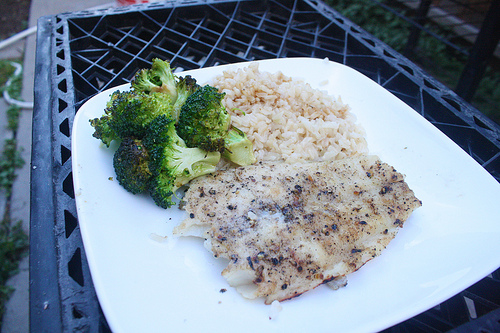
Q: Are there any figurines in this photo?
A: No, there are no figurines.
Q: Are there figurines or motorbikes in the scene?
A: No, there are no figurines or motorbikes.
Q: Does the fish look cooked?
A: Yes, the fish is cooked.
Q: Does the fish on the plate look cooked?
A: Yes, the fish is cooked.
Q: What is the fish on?
A: The fish is on the plate.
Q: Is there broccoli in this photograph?
A: Yes, there is broccoli.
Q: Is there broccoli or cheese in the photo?
A: Yes, there is broccoli.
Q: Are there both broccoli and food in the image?
A: Yes, there are both broccoli and food.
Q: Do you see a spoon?
A: No, there are no spoons.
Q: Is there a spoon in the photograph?
A: No, there are no spoons.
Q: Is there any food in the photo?
A: Yes, there is food.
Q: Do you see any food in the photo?
A: Yes, there is food.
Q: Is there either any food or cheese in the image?
A: Yes, there is food.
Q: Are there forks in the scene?
A: No, there are no forks.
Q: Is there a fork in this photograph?
A: No, there are no forks.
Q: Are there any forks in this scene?
A: No, there are no forks.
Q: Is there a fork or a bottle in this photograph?
A: No, there are no forks or bottles.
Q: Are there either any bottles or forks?
A: No, there are no forks or bottles.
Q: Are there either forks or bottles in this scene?
A: No, there are no forks or bottles.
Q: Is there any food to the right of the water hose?
A: Yes, there is food to the right of the water hose.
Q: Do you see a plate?
A: Yes, there is a plate.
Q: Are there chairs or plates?
A: Yes, there is a plate.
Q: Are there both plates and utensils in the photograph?
A: No, there is a plate but no utensils.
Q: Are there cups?
A: No, there are no cups.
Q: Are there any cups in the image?
A: No, there are no cups.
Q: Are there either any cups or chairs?
A: No, there are no cups or chairs.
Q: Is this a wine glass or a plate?
A: This is a plate.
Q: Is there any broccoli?
A: Yes, there is broccoli.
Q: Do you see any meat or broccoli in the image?
A: Yes, there is broccoli.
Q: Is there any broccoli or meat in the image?
A: Yes, there is broccoli.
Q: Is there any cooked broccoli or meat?
A: Yes, there is cooked broccoli.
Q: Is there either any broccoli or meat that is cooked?
A: Yes, the broccoli is cooked.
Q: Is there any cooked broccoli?
A: Yes, there is cooked broccoli.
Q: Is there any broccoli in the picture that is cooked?
A: Yes, there is broccoli that is cooked.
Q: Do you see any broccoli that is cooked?
A: Yes, there is broccoli that is cooked.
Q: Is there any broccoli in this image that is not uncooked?
A: Yes, there is cooked broccoli.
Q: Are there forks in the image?
A: No, there are no forks.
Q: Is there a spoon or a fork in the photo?
A: No, there are no forks or spoons.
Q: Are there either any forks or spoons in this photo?
A: No, there are no forks or spoons.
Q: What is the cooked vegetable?
A: The vegetable is broccoli.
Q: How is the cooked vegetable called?
A: The vegetable is broccoli.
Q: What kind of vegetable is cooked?
A: The vegetable is broccoli.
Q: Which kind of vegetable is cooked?
A: The vegetable is broccoli.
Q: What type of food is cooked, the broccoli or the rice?
A: The broccoli is cooked.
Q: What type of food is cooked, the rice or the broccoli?
A: The broccoli is cooked.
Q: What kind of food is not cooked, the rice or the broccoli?
A: The rice is not cooked.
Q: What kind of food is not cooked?
A: The food is rice.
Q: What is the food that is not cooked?
A: The food is rice.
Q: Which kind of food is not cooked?
A: The food is rice.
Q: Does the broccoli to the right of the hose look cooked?
A: Yes, the broccoli is cooked.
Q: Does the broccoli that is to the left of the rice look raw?
A: No, the broccoli is cooked.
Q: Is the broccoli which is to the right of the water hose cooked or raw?
A: The broccoli is cooked.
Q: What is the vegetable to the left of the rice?
A: The vegetable is broccoli.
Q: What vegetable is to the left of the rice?
A: The vegetable is broccoli.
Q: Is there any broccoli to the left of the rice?
A: Yes, there is broccoli to the left of the rice.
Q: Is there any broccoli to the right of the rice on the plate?
A: No, the broccoli is to the left of the rice.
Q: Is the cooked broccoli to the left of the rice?
A: Yes, the broccoli is to the left of the rice.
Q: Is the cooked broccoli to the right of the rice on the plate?
A: No, the broccoli is to the left of the rice.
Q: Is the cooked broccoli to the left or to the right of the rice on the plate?
A: The broccoli is to the left of the rice.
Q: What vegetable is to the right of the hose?
A: The vegetable is broccoli.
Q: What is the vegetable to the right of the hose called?
A: The vegetable is broccoli.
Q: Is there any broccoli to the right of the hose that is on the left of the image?
A: Yes, there is broccoli to the right of the hose.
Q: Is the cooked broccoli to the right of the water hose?
A: Yes, the broccoli is to the right of the water hose.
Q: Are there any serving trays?
A: No, there are no serving trays.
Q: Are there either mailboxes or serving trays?
A: No, there are no serving trays or mailboxes.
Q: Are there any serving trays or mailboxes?
A: No, there are no serving trays or mailboxes.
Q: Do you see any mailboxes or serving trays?
A: No, there are no serving trays or mailboxes.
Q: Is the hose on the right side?
A: No, the hose is on the left of the image.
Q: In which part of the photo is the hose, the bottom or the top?
A: The hose is in the top of the image.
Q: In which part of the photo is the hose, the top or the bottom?
A: The hose is in the top of the image.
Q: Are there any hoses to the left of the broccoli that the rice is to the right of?
A: Yes, there is a hose to the left of the broccoli.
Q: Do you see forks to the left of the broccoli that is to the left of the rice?
A: No, there is a hose to the left of the broccoli.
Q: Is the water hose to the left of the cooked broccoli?
A: Yes, the water hose is to the left of the broccoli.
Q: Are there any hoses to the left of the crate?
A: Yes, there is a hose to the left of the crate.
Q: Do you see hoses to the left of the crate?
A: Yes, there is a hose to the left of the crate.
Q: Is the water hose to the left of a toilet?
A: No, the water hose is to the left of the crate.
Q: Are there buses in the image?
A: No, there are no buses.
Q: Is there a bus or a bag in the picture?
A: No, there are no buses or bags.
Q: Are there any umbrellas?
A: No, there are no umbrellas.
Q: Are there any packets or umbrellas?
A: No, there are no umbrellas or packets.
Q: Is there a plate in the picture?
A: Yes, there is a plate.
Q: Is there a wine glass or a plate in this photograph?
A: Yes, there is a plate.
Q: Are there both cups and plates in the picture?
A: No, there is a plate but no cups.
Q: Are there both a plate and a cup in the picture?
A: No, there is a plate but no cups.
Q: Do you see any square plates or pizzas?
A: Yes, there is a square plate.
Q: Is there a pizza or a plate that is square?
A: Yes, the plate is square.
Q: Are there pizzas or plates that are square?
A: Yes, the plate is square.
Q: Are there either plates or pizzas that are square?
A: Yes, the plate is square.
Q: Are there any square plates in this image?
A: Yes, there is a square plate.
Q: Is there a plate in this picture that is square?
A: Yes, there is a plate that is square.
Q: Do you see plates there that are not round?
A: Yes, there is a square plate.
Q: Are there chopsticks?
A: No, there are no chopsticks.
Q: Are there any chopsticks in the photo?
A: No, there are no chopsticks.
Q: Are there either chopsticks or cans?
A: No, there are no chopsticks or cans.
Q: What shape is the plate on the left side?
A: The plate is square.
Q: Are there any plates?
A: Yes, there is a plate.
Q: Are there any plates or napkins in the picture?
A: Yes, there is a plate.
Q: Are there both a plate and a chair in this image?
A: No, there is a plate but no chairs.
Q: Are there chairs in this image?
A: No, there are no chairs.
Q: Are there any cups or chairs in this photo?
A: No, there are no chairs or cups.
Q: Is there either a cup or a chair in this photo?
A: No, there are no chairs or cups.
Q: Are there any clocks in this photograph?
A: No, there are no clocks.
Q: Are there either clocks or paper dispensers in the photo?
A: No, there are no clocks or paper dispensers.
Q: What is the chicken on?
A: The chicken is on the plate.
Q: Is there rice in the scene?
A: Yes, there is rice.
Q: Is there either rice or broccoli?
A: Yes, there is rice.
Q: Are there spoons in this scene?
A: No, there are no spoons.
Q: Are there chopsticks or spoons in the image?
A: No, there are no spoons or chopsticks.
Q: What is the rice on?
A: The rice is on the plate.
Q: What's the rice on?
A: The rice is on the plate.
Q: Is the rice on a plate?
A: Yes, the rice is on a plate.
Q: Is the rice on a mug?
A: No, the rice is on a plate.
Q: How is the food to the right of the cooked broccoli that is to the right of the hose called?
A: The food is rice.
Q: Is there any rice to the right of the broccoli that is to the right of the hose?
A: Yes, there is rice to the right of the broccoli.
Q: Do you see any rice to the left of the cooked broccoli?
A: No, the rice is to the right of the broccoli.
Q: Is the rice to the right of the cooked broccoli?
A: Yes, the rice is to the right of the broccoli.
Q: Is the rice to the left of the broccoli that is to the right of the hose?
A: No, the rice is to the right of the broccoli.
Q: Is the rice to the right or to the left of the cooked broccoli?
A: The rice is to the right of the broccoli.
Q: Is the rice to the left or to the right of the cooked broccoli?
A: The rice is to the right of the broccoli.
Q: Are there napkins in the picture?
A: No, there are no napkins.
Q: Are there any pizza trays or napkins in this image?
A: No, there are no napkins or pizza trays.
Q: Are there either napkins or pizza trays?
A: No, there are no napkins or pizza trays.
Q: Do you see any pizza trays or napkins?
A: No, there are no napkins or pizza trays.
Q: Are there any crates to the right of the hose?
A: Yes, there is a crate to the right of the hose.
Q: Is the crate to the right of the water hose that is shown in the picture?
A: Yes, the crate is to the right of the water hose.